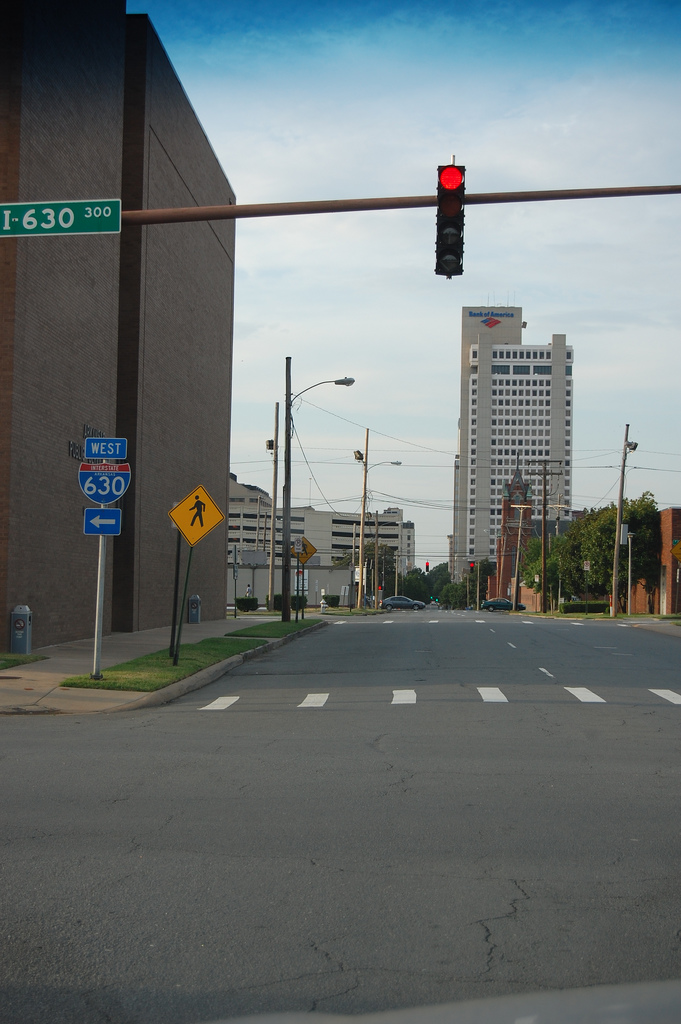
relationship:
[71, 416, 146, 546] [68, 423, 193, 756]
sign on post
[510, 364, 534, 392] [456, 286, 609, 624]
window on building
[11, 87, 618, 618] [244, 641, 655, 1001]
buildings in area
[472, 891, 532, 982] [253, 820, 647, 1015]
crack on cement